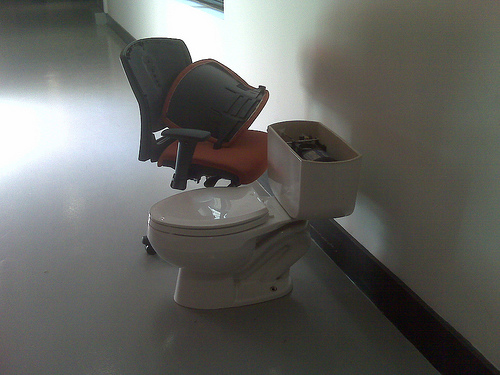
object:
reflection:
[3, 81, 110, 176]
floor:
[3, 5, 448, 370]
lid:
[147, 184, 266, 236]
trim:
[116, 25, 500, 372]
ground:
[437, 133, 490, 167]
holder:
[265, 120, 363, 221]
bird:
[371, 17, 474, 139]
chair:
[119, 37, 267, 190]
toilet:
[147, 121, 366, 311]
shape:
[393, 156, 471, 304]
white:
[171, 195, 250, 219]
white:
[178, 242, 280, 293]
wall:
[106, 0, 493, 370]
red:
[216, 143, 251, 165]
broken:
[161, 58, 271, 150]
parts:
[286, 132, 337, 163]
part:
[92, 344, 152, 375]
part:
[167, 343, 298, 375]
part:
[117, 286, 255, 321]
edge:
[163, 217, 251, 235]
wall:
[65, 169, 148, 328]